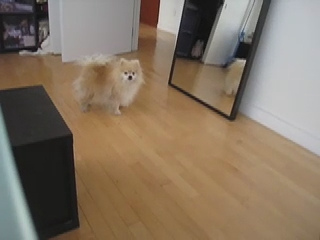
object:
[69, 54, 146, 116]
pomeranian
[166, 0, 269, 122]
mirror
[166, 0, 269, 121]
frame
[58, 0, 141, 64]
door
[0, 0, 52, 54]
shelf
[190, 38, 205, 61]
cat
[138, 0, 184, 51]
hall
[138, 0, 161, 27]
door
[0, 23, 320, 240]
flooring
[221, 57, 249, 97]
reflection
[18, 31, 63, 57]
cloth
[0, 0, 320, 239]
room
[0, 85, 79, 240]
box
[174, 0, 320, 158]
wall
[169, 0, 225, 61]
reflection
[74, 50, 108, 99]
tail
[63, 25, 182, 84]
doorway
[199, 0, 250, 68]
reflection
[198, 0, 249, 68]
door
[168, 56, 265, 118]
reflection